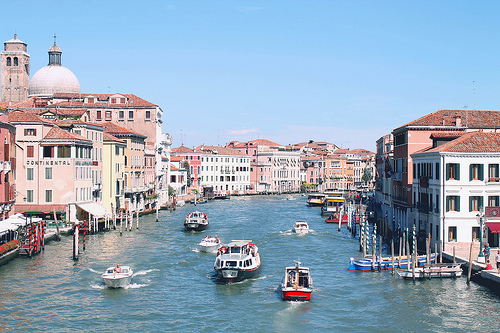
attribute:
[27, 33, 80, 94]
dome — white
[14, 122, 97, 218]
building — tall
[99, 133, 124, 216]
building — tall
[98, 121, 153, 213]
building — tall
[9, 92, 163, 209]
building — tall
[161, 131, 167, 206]
building — tall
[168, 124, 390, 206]
buildings — white 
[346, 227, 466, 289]
boats — canal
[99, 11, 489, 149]
sky — blue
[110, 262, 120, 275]
shirt — red 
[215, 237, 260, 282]
boat — largest, black, white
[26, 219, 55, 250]
pylons — red striped, canal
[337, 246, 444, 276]
boats — white 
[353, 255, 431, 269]
boat — blue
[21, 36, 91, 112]
steeple — dome